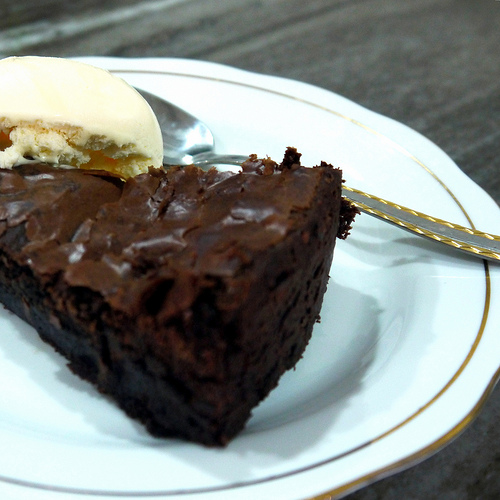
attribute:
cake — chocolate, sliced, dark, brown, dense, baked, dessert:
[3, 159, 354, 411]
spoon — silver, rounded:
[135, 85, 495, 269]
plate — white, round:
[3, 47, 474, 499]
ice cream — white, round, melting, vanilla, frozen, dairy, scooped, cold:
[5, 54, 174, 167]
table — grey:
[30, 6, 498, 165]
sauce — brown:
[25, 120, 135, 168]